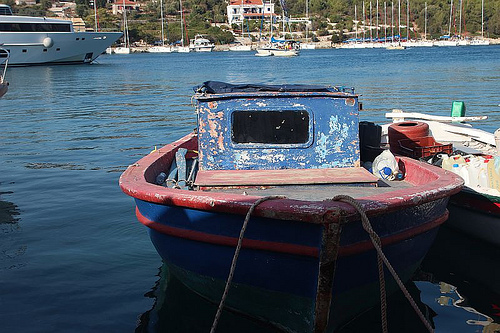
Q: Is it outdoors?
A: Yes, it is outdoors.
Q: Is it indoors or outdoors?
A: It is outdoors.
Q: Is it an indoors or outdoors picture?
A: It is outdoors.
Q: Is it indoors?
A: No, it is outdoors.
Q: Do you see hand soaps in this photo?
A: No, there are no hand soaps.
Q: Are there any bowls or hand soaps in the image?
A: No, there are no hand soaps or bowls.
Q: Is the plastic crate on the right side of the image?
A: Yes, the crate is on the right of the image.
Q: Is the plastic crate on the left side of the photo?
A: No, the crate is on the right of the image.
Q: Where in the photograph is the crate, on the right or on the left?
A: The crate is on the right of the image.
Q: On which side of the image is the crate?
A: The crate is on the right of the image.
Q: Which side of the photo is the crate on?
A: The crate is on the right of the image.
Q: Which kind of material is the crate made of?
A: The crate is made of plastic.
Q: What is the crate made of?
A: The crate is made of plastic.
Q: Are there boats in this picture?
A: Yes, there is a boat.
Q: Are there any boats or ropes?
A: Yes, there is a boat.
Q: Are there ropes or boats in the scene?
A: Yes, there is a boat.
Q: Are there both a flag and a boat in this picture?
A: No, there is a boat but no flags.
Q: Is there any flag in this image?
A: No, there are no flags.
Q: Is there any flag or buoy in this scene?
A: No, there are no flags or buoys.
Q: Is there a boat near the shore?
A: Yes, there is a boat near the shore.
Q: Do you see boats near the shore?
A: Yes, there is a boat near the shore.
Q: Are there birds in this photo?
A: No, there are no birds.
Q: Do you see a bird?
A: No, there are no birds.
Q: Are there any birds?
A: No, there are no birds.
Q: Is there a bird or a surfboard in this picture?
A: No, there are no birds or surfboards.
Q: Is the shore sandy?
A: Yes, the shore is sandy.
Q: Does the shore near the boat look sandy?
A: Yes, the shore is sandy.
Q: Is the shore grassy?
A: No, the shore is sandy.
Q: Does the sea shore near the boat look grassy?
A: No, the shore is sandy.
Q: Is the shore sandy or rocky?
A: The shore is sandy.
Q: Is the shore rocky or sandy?
A: The shore is sandy.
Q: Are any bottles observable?
A: Yes, there is a bottle.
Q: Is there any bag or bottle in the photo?
A: Yes, there is a bottle.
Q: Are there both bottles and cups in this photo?
A: No, there is a bottle but no cups.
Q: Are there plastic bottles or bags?
A: Yes, there is a plastic bottle.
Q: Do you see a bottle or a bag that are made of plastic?
A: Yes, the bottle is made of plastic.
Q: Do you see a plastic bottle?
A: Yes, there is a bottle that is made of plastic.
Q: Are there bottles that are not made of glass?
A: Yes, there is a bottle that is made of plastic.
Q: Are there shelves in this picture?
A: No, there are no shelves.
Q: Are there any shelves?
A: No, there are no shelves.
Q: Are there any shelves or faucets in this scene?
A: No, there are no shelves or faucets.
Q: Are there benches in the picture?
A: No, there are no benches.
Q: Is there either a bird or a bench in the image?
A: No, there are no benches or birds.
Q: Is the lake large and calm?
A: Yes, the lake is large and calm.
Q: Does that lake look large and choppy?
A: No, the lake is large but calm.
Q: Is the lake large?
A: Yes, the lake is large.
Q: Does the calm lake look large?
A: Yes, the lake is large.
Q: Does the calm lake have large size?
A: Yes, the lake is large.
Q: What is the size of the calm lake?
A: The lake is large.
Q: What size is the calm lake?
A: The lake is large.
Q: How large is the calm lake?
A: The lake is large.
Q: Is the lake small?
A: No, the lake is large.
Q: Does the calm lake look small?
A: No, the lake is large.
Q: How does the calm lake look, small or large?
A: The lake is large.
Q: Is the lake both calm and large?
A: Yes, the lake is calm and large.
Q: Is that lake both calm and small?
A: No, the lake is calm but large.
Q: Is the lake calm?
A: Yes, the lake is calm.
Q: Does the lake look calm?
A: Yes, the lake is calm.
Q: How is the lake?
A: The lake is calm.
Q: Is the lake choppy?
A: No, the lake is calm.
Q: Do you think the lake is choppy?
A: No, the lake is calm.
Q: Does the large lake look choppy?
A: No, the lake is calm.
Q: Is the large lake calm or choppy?
A: The lake is calm.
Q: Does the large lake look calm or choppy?
A: The lake is calm.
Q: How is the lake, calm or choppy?
A: The lake is calm.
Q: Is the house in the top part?
A: Yes, the house is in the top of the image.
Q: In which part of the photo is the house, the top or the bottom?
A: The house is in the top of the image.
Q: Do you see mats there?
A: No, there are no mats.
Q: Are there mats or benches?
A: No, there are no mats or benches.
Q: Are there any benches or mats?
A: No, there are no mats or benches.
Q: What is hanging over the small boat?
A: The rope is hanging over the boat.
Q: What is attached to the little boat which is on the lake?
A: The rope is attached to the boat.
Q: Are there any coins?
A: No, there are no coins.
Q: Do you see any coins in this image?
A: No, there are no coins.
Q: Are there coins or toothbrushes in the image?
A: No, there are no coins or toothbrushes.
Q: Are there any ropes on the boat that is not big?
A: Yes, there is a rope on the boat.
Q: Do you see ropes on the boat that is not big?
A: Yes, there is a rope on the boat.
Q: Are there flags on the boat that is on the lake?
A: No, there is a rope on the boat.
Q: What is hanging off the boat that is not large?
A: The rope is hanging off the boat.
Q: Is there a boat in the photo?
A: Yes, there is a boat.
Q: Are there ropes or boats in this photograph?
A: Yes, there is a boat.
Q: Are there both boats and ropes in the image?
A: Yes, there are both a boat and a rope.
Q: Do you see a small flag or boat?
A: Yes, there is a small boat.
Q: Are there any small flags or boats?
A: Yes, there is a small boat.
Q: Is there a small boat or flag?
A: Yes, there is a small boat.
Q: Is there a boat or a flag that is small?
A: Yes, the boat is small.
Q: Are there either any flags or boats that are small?
A: Yes, the boat is small.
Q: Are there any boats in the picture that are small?
A: Yes, there is a small boat.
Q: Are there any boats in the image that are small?
A: Yes, there is a boat that is small.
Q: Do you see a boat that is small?
A: Yes, there is a boat that is small.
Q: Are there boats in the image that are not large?
A: Yes, there is a small boat.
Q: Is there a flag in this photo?
A: No, there are no flags.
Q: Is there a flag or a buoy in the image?
A: No, there are no flags or buoys.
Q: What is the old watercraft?
A: The watercraft is a boat.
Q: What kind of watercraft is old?
A: The watercraft is a boat.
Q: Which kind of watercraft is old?
A: The watercraft is a boat.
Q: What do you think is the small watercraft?
A: The watercraft is a boat.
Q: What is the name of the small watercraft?
A: The watercraft is a boat.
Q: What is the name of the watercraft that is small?
A: The watercraft is a boat.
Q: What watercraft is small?
A: The watercraft is a boat.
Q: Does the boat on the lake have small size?
A: Yes, the boat is small.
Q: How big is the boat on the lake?
A: The boat is small.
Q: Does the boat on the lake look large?
A: No, the boat is small.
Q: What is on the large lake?
A: The boat is on the lake.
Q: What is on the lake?
A: The boat is on the lake.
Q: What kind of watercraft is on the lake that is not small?
A: The watercraft is a boat.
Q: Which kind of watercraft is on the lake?
A: The watercraft is a boat.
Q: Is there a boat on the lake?
A: Yes, there is a boat on the lake.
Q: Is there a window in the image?
A: Yes, there is a window.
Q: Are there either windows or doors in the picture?
A: Yes, there is a window.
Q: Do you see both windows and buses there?
A: No, there is a window but no buses.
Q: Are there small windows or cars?
A: Yes, there is a small window.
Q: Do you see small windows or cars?
A: Yes, there is a small window.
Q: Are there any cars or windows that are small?
A: Yes, the window is small.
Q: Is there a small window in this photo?
A: Yes, there is a small window.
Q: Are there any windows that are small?
A: Yes, there is a window that is small.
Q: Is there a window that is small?
A: Yes, there is a window that is small.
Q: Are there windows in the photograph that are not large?
A: Yes, there is a small window.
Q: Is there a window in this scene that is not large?
A: Yes, there is a small window.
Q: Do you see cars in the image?
A: No, there are no cars.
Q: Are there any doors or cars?
A: No, there are no cars or doors.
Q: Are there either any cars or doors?
A: No, there are no cars or doors.